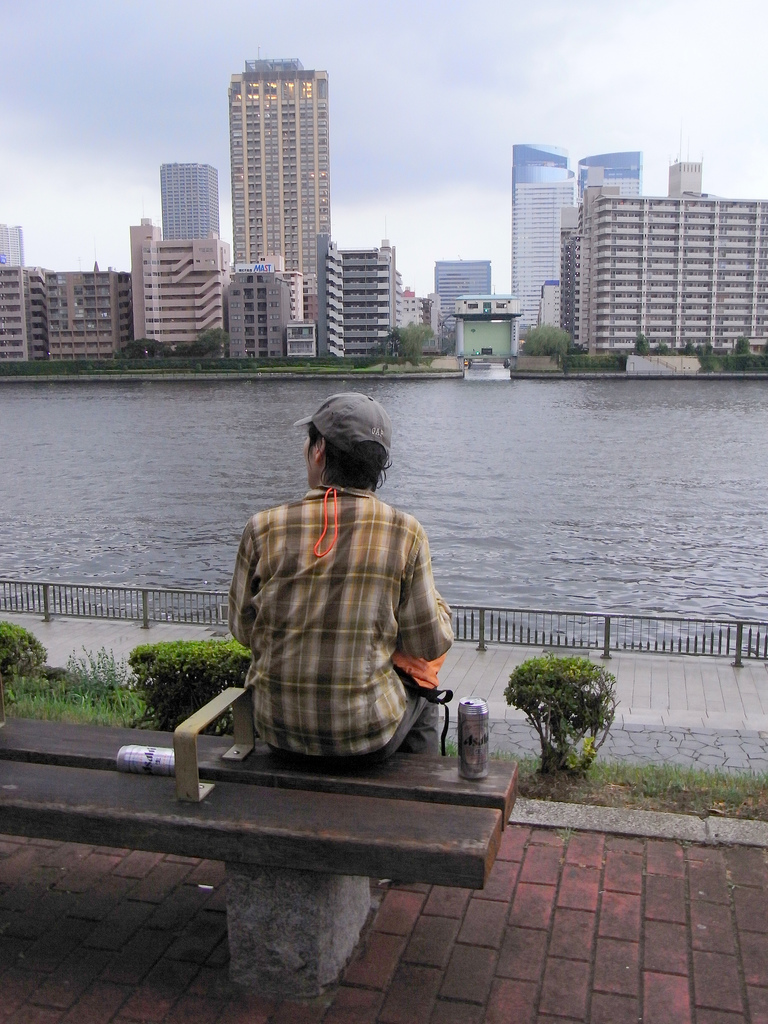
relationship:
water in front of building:
[517, 412, 656, 588] [569, 160, 744, 368]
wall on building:
[284, 215, 348, 301] [324, 237, 402, 352]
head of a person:
[290, 403, 394, 492] [233, 385, 450, 762]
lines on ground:
[492, 878, 705, 986] [4, 617, 765, 1022]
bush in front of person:
[507, 645, 616, 776] [237, 399, 446, 776]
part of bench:
[229, 865, 376, 994] [6, 703, 519, 993]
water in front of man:
[2, 368, 767, 643] [236, 368, 454, 760]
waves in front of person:
[491, 485, 765, 621] [243, 390, 458, 769]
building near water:
[109, 618, 558, 783] [445, 329, 680, 573]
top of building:
[180, 42, 383, 142] [561, 122, 761, 398]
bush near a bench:
[507, 644, 616, 775] [33, 667, 661, 967]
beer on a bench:
[454, 692, 489, 780] [20, 661, 609, 908]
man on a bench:
[223, 391, 449, 750] [20, 621, 572, 873]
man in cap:
[223, 391, 449, 750] [260, 389, 399, 470]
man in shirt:
[223, 391, 449, 750] [232, 497, 469, 768]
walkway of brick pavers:
[41, 894, 582, 1018] [409, 195, 506, 372]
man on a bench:
[131, 358, 642, 864] [18, 708, 589, 958]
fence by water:
[0, 548, 766, 662] [483, 416, 608, 511]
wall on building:
[219, 51, 340, 116] [226, 57, 328, 285]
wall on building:
[215, 50, 339, 142] [132, 226, 224, 352]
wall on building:
[568, 184, 742, 371] [575, 191, 767, 364]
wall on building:
[316, 223, 406, 365] [428, 259, 497, 331]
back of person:
[233, 488, 448, 739] [233, 385, 450, 762]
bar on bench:
[156, 664, 259, 816] [2, 703, 518, 958]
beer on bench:
[454, 692, 489, 780] [10, 700, 522, 958]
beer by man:
[454, 692, 489, 780] [190, 384, 453, 786]